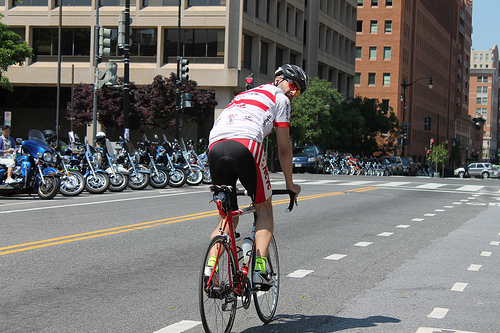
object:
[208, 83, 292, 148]
shirt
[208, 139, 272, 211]
shorts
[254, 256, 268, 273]
sock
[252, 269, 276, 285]
shoe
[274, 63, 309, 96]
helmet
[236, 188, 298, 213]
handle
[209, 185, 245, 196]
seat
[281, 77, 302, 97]
glasses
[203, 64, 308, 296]
man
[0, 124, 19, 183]
person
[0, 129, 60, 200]
motorcycle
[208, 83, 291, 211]
uniform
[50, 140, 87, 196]
motorcycles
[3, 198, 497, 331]
street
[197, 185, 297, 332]
bicycle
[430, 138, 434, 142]
stoplight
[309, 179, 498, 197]
crosswalk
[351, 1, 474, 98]
building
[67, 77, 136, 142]
trees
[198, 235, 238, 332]
wheel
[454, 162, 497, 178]
car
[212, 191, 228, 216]
pack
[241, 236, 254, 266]
bottle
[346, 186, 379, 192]
stripes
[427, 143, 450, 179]
tree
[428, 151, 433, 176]
post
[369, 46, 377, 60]
windows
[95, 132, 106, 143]
helmet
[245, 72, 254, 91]
light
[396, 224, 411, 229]
line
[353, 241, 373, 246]
line